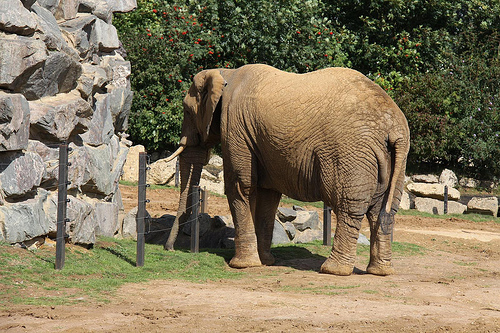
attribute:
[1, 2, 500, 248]
rock — grey, gray, wall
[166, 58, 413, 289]
elephant — brown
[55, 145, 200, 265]
post — black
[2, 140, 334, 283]
fence — wire, grey, metal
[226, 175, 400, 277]
leg — wrinkled, brown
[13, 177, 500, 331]
ground — brown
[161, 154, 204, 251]
trunk — long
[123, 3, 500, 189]
tree — green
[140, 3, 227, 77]
bloom — red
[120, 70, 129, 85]
bird — white, flying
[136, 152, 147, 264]
pole — support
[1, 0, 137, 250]
wall — rock